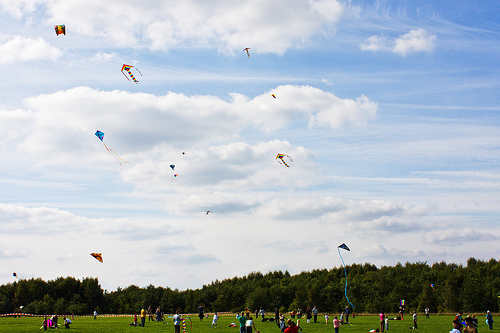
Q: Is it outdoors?
A: Yes, it is outdoors.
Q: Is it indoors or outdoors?
A: It is outdoors.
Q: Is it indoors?
A: No, it is outdoors.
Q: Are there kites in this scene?
A: Yes, there is a kite.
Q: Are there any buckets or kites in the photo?
A: Yes, there is a kite.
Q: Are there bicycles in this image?
A: No, there are no bicycles.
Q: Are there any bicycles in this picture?
A: No, there are no bicycles.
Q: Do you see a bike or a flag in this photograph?
A: No, there are no bikes or flags.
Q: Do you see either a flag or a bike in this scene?
A: No, there are no bikes or flags.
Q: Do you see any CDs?
A: No, there are no cds.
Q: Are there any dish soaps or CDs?
A: No, there are no CDs or dish soaps.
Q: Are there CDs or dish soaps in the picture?
A: No, there are no CDs or dish soaps.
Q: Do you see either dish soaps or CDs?
A: No, there are no CDs or dish soaps.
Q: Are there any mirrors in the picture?
A: No, there are no mirrors.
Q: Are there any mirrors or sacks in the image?
A: No, there are no mirrors or sacks.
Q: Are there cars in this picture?
A: No, there are no cars.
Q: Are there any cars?
A: No, there are no cars.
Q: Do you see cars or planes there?
A: No, there are no cars or planes.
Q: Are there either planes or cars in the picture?
A: No, there are no cars or planes.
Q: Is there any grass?
A: Yes, there is grass.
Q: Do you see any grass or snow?
A: Yes, there is grass.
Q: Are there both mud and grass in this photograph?
A: No, there is grass but no mud.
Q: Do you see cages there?
A: No, there are no cages.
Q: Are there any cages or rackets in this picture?
A: No, there are no cages or rackets.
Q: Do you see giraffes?
A: No, there are no giraffes.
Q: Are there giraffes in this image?
A: No, there are no giraffes.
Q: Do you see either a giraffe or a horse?
A: No, there are no giraffes or horses.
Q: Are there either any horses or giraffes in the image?
A: No, there are no giraffes or horses.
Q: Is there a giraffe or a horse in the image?
A: No, there are no giraffes or horses.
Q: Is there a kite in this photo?
A: Yes, there is a kite.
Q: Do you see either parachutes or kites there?
A: Yes, there is a kite.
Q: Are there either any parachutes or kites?
A: Yes, there is a kite.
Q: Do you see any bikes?
A: No, there are no bikes.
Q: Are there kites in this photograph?
A: Yes, there is a kite.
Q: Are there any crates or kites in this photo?
A: Yes, there is a kite.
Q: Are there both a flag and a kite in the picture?
A: No, there is a kite but no flags.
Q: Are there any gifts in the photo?
A: No, there are no gifts.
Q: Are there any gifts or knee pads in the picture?
A: No, there are no gifts or knee pads.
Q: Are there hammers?
A: No, there are no hammers.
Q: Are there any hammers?
A: No, there are no hammers.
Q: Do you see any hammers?
A: No, there are no hammers.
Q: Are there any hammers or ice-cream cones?
A: No, there are no hammers or ice-cream cones.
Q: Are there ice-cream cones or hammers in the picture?
A: No, there are no hammers or ice-cream cones.